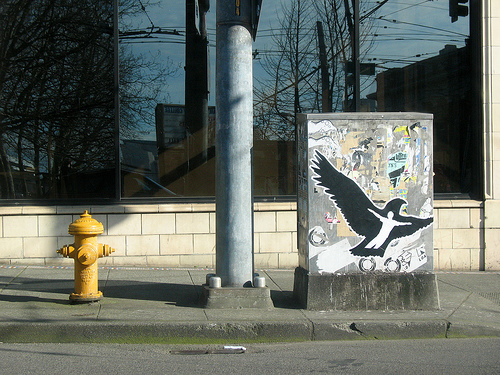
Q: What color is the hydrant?
A: Yellow.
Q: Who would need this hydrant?
A: A firefighter.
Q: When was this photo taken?
A: During the daytime.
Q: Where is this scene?
A: In a city.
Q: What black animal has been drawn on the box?
A: Bird.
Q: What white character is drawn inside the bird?
A: A person.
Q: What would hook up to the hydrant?
A: A hose.